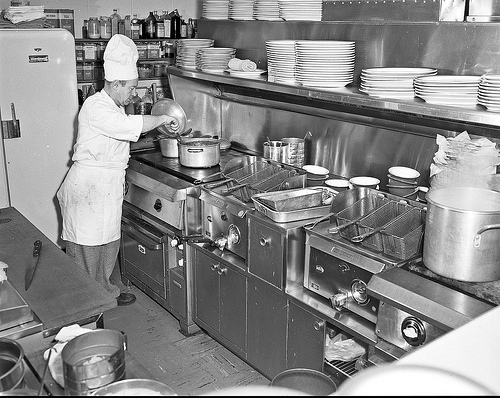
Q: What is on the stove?
A: Pots.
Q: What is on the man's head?
A: A hat.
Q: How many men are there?
A: One.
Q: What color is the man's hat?
A: White.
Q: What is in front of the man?
A: The stove.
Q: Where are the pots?
A: On the stove.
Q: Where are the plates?
A: Over the stove.